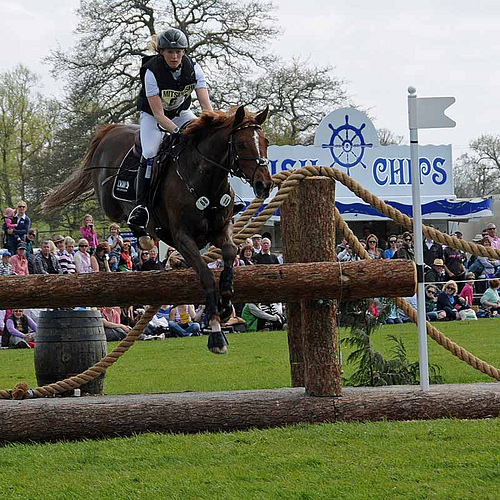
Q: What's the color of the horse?
A: Brown.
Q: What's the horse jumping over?
A: Logs.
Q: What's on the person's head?
A: Helmet.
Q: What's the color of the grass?
A: Green.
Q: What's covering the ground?
A: Grass.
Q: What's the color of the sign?
A: Blue and white.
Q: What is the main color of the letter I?
A: Blue.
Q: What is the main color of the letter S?
A: BLUE.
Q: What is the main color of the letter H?
A: Blue.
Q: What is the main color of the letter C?
A: Blue.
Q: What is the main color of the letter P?
A: Blue.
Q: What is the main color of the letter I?
A: Black.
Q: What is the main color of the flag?
A: White.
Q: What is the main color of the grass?
A: Green.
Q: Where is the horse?
A: In the air.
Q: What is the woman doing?
A: Riding.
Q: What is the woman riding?
A: The horse.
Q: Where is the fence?
A: In the field.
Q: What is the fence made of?
A: Wood.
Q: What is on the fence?
A: Rope.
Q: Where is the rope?
A: On the fence.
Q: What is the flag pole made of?
A: Metal.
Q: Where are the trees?
A: Behind the crowd.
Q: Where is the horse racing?
A: On field.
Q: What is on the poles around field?
A: A rope.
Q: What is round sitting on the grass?
A: A barrel.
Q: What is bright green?
A: Grass.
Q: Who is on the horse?
A: The rider.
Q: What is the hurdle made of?
A: Logs.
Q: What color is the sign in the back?
A: Blue and white.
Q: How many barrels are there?
A: One.